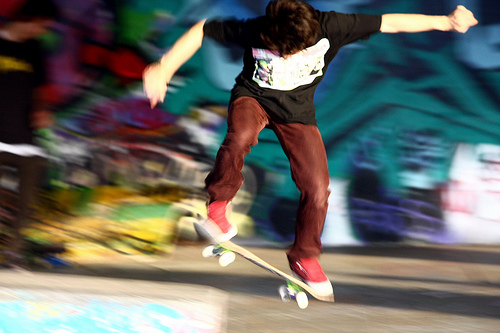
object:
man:
[141, 0, 480, 297]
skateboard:
[191, 222, 336, 309]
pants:
[200, 89, 331, 259]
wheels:
[217, 249, 235, 267]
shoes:
[284, 251, 332, 295]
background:
[0, 1, 498, 332]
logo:
[249, 37, 333, 91]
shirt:
[200, 12, 384, 127]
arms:
[324, 10, 451, 47]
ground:
[0, 243, 498, 333]